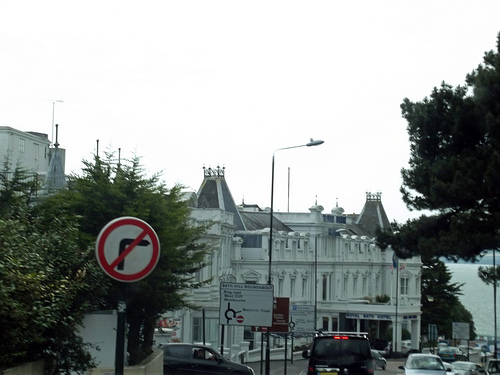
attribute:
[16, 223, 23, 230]
leaf — green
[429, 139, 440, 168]
leaf — green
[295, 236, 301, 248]
window — glass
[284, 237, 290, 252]
window — glass